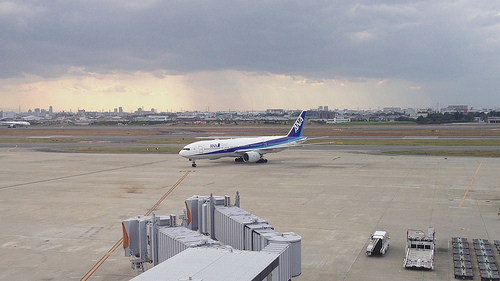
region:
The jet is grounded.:
[174, 108, 313, 167]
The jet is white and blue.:
[173, 108, 311, 165]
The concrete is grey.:
[303, 158, 415, 215]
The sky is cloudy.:
[21, 13, 428, 102]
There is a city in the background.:
[15, 107, 469, 124]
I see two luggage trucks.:
[365, 222, 447, 274]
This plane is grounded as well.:
[0, 119, 43, 129]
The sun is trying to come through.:
[100, 41, 307, 112]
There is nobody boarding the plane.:
[103, 185, 306, 277]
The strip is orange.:
[76, 148, 203, 271]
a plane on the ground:
[178, 64, 481, 192]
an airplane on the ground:
[143, 77, 372, 225]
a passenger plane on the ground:
[140, 66, 304, 178]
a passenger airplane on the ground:
[158, 79, 390, 233]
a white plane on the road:
[179, 68, 307, 203]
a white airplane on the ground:
[172, 81, 307, 196]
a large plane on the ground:
[134, 66, 293, 191]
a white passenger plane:
[161, 78, 368, 210]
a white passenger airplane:
[132, 78, 344, 217]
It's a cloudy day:
[11, 2, 458, 107]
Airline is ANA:
[175, 105, 312, 172]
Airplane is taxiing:
[169, 101, 319, 182]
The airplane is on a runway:
[0, 105, 39, 136]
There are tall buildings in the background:
[16, 83, 186, 129]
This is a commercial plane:
[168, 103, 323, 178]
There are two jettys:
[93, 178, 300, 280]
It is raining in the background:
[142, 33, 298, 128]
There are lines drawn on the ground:
[36, 150, 491, 275]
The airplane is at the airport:
[96, 97, 321, 279]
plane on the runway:
[172, 101, 323, 171]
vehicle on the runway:
[363, 223, 390, 263]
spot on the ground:
[114, 172, 149, 199]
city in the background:
[335, 100, 481, 130]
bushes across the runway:
[419, 111, 481, 126]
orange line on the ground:
[146, 184, 182, 203]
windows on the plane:
[180, 143, 196, 155]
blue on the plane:
[256, 135, 290, 148]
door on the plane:
[257, 138, 271, 150]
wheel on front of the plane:
[185, 158, 200, 172]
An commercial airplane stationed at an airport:
[172, 103, 314, 171]